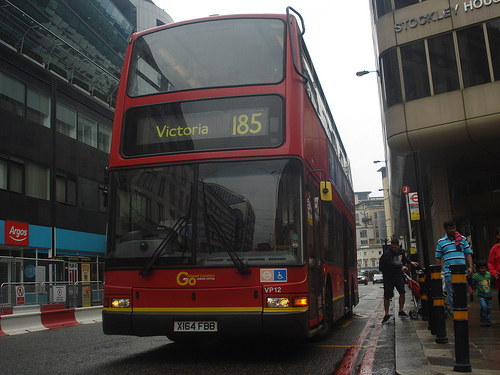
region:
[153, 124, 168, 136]
yellow letter on bus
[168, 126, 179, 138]
yellow letter on bus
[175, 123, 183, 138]
yellow letter on bus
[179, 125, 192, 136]
yellow letter on bus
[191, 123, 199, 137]
yellow letter on bus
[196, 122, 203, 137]
yellow letter on bus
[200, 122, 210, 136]
yellow letter on bus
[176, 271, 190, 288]
yellow letter on bus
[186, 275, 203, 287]
yellow letter on bus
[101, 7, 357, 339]
A bus is stopped on the street.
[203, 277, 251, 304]
The bus is red.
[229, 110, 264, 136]
The number 185 is on the bus.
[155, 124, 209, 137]
The word Victoria is on the bus.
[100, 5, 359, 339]
The bus is a double decker bus.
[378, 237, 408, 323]
A person is on the sidewalk.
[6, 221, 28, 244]
A sign is on the building.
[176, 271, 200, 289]
The word Go is on the bus.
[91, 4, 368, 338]
Red double decker bus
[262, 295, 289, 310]
right head light on the red double decker bus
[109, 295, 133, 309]
Left head light of the double decker bus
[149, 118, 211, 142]
Destination of the bus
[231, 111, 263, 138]
number for the bus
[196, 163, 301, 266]
drivers side windshield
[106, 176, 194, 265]
passenger side windshield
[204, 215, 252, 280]
drivers side windshield wiper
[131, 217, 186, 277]
passenger side windshield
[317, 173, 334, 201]
rear view mirror for the driver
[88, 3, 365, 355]
a double decker bus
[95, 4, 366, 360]
a red double decker bus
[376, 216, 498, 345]
people walking in the sidewalk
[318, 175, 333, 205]
side mirror of the bus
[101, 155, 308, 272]
windshield of the bus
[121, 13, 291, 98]
windshield of the upper deck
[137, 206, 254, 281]
wipers of the bus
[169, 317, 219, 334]
a plate number of the bus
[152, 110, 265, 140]
a sign on the bus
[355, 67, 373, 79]
a street light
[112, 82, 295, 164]
Bus that says Victoria 185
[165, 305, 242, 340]
Plate number that reads X164FBB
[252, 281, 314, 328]
Headlight on bus with turn signal light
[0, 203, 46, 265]
Company logo on a blue wall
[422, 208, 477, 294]
Dark color man with a blue stripe t shirt on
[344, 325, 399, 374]
Red painted stripe on concrete road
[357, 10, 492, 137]
Large building with tall windows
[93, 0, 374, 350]
Tall buss red with upper deck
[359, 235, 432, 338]
Man at edge of red line looking down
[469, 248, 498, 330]
Small boy with jeans and a green t shirt